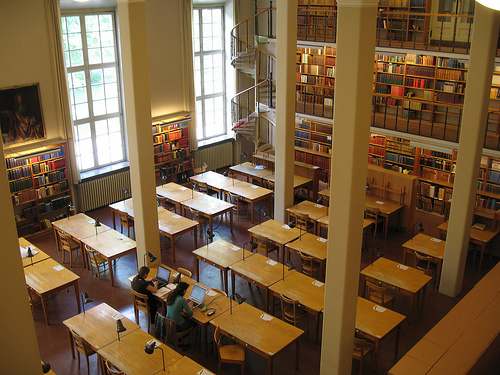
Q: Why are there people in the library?
A: To study.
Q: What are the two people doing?
A: Looking at their laptop.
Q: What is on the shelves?
A: Books.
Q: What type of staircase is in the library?
A: Spiral.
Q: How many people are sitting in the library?
A: Two.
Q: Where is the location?
A: Library.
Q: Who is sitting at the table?
A: A man and a woman.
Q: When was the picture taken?
A: Daytime.